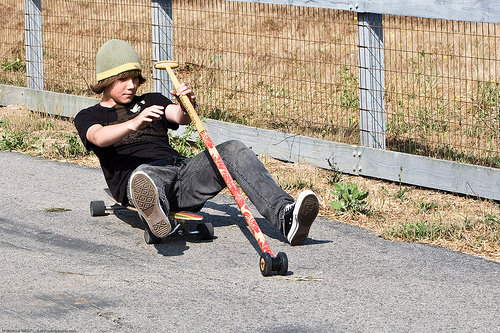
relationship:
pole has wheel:
[153, 59, 284, 257] [253, 251, 278, 277]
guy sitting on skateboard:
[73, 35, 321, 248] [89, 185, 216, 249]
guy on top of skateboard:
[73, 35, 321, 248] [89, 185, 216, 249]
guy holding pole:
[73, 35, 321, 248] [153, 59, 284, 257]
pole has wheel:
[153, 59, 284, 257] [88, 197, 111, 219]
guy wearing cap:
[73, 35, 321, 248] [93, 35, 143, 83]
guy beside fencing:
[73, 35, 321, 248] [1, 1, 498, 173]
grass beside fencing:
[0, 3, 500, 159] [1, 1, 498, 173]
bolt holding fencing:
[353, 148, 365, 161] [1, 1, 498, 173]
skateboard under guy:
[89, 185, 216, 249] [73, 35, 321, 248]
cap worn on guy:
[93, 35, 143, 83] [73, 35, 321, 248]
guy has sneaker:
[73, 35, 321, 248] [278, 188, 322, 248]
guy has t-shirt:
[73, 35, 321, 248] [73, 90, 188, 211]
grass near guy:
[0, 3, 500, 159] [73, 35, 321, 248]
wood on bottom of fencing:
[1, 81, 500, 207] [1, 1, 498, 173]